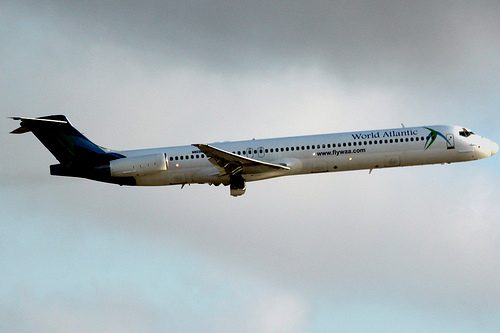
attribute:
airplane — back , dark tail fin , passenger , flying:
[11, 87, 482, 198]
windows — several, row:
[294, 135, 424, 151]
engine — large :
[109, 148, 176, 184]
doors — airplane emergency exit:
[441, 130, 457, 150]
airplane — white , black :
[10, 92, 484, 209]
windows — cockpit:
[294, 138, 423, 150]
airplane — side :
[20, 103, 478, 203]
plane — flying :
[9, 97, 484, 207]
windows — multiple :
[322, 136, 428, 149]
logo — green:
[428, 125, 450, 150]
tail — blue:
[6, 109, 132, 192]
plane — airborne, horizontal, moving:
[10, 108, 495, 200]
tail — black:
[8, 107, 129, 185]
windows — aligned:
[165, 133, 436, 164]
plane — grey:
[5, 106, 497, 184]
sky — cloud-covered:
[3, 1, 496, 331]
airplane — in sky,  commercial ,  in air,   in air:
[7, 113, 497, 199]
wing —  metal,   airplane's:
[191, 142, 290, 188]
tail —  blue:
[9, 114, 136, 186]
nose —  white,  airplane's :
[479, 138, 498, 156]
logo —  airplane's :
[421, 125, 450, 146]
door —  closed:
[443, 134, 453, 150]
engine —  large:
[94, 152, 169, 176]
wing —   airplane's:
[190, 143, 288, 179]